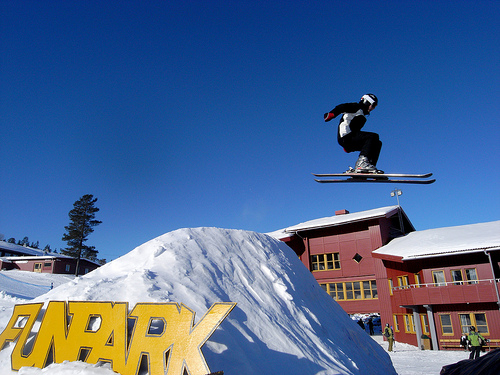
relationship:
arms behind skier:
[307, 104, 355, 127] [325, 66, 407, 190]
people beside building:
[387, 316, 490, 359] [258, 200, 496, 343]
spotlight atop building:
[386, 182, 405, 204] [258, 200, 496, 343]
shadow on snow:
[191, 202, 353, 371] [137, 238, 330, 365]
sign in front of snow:
[31, 285, 207, 373] [137, 238, 330, 365]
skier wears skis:
[325, 66, 407, 190] [328, 160, 436, 189]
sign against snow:
[31, 285, 207, 373] [137, 238, 330, 365]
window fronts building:
[344, 250, 363, 264] [258, 200, 496, 343]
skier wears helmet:
[325, 66, 407, 190] [359, 91, 393, 100]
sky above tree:
[93, 4, 245, 119] [68, 195, 95, 269]